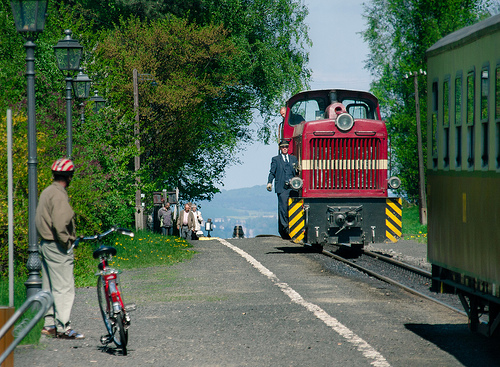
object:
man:
[266, 140, 301, 242]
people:
[175, 203, 196, 241]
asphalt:
[135, 233, 500, 366]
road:
[217, 236, 493, 365]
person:
[190, 204, 204, 241]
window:
[430, 81, 439, 168]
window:
[443, 80, 451, 170]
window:
[287, 95, 328, 125]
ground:
[235, 236, 281, 266]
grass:
[135, 232, 191, 265]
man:
[36, 155, 87, 341]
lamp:
[8, 0, 47, 41]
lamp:
[71, 66, 93, 99]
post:
[66, 77, 73, 159]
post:
[81, 106, 86, 129]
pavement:
[100, 241, 358, 367]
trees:
[91, 17, 230, 166]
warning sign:
[287, 197, 306, 242]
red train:
[275, 86, 405, 251]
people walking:
[157, 203, 174, 236]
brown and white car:
[231, 225, 247, 239]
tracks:
[352, 242, 473, 326]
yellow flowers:
[124, 258, 129, 261]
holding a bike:
[31, 157, 137, 357]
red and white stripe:
[50, 158, 75, 171]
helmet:
[50, 158, 74, 172]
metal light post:
[24, 40, 43, 297]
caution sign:
[385, 196, 403, 244]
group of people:
[142, 202, 206, 237]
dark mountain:
[186, 181, 294, 239]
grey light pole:
[131, 67, 142, 231]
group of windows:
[426, 69, 500, 170]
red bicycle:
[66, 227, 138, 356]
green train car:
[423, 13, 500, 349]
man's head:
[280, 107, 287, 118]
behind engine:
[209, 190, 258, 222]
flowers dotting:
[139, 238, 143, 241]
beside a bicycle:
[34, 158, 87, 339]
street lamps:
[50, 28, 83, 156]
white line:
[214, 238, 392, 367]